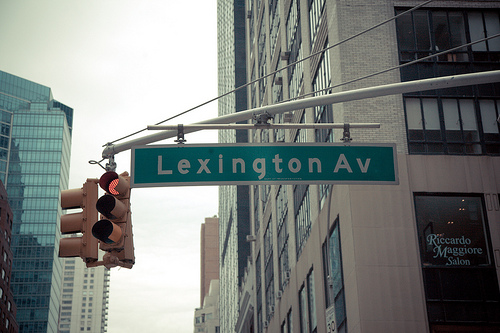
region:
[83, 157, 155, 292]
yellow hanging traffic signal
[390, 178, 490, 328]
window of Riccardo Maggiore Salon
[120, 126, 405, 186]
sign for Lexington Avenue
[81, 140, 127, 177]
wire connected to the traffic signal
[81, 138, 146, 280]
traffic signal with red light illuminated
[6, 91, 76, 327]
building with a lot of windows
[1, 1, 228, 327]
white overcast sky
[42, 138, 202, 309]
two traffic signals hang from the pole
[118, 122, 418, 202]
green and white street sign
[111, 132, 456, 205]
rectangular street sign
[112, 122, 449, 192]
Green sign on metal pole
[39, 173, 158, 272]
Two traffic lights hanging from a pole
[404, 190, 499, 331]
Window with decals on them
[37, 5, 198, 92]
The sky is fully cloudy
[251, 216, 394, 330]
Side of building full of windows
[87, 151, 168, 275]
Traffic light is red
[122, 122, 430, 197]
The sign is for Lexington Avenue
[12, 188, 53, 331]
Reflection on side of building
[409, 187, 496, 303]
Window for the salon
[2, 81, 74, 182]
Reflective windows on side of building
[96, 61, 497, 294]
a green and white sign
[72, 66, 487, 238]
a green and white street sign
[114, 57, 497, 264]
a green and white sign hanging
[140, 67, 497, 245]
a green and white street sign hanging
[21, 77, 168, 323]
a traffic light hanging on pole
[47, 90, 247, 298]
a traffic light on pole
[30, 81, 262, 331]
a traffic light hanging from metal pole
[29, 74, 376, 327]
traffic light next to street sign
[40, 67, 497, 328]
traffic light next to sign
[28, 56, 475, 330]
a light next to street sign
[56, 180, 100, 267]
yellow traffic light next to yellow traffic light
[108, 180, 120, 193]
light is red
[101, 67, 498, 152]
gray metal arm supports traffic light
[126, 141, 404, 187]
green sign under arm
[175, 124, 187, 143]
metal bracket on sign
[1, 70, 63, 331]
glass building to the left of traffic light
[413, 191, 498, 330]
window on building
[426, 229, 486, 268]
white writing on building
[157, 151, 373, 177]
white writing on sign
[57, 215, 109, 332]
white building behind traffic light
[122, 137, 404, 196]
name of street on sign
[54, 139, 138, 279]
two traffic lights on pole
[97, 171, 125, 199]
glowing top light under cover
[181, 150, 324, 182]
white letters on green background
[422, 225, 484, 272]
name of business on window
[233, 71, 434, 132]
curved metal horizontal pole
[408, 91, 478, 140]
white shades on window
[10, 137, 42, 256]
reflection on glass window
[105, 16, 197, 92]
white cloud cover in sky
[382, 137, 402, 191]
white outline on sign